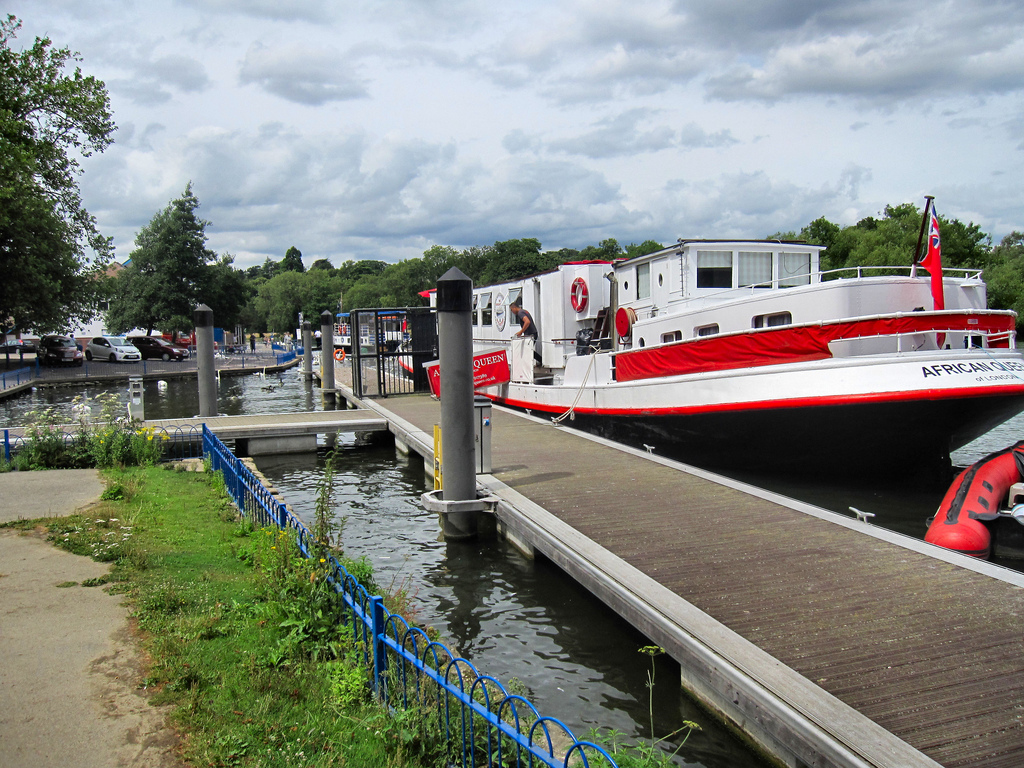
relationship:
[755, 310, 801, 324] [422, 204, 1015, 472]
window on ship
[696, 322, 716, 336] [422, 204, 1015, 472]
window on ship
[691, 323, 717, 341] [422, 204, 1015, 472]
window on ship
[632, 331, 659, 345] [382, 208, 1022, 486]
glass window on boat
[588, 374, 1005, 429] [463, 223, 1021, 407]
red trim on boat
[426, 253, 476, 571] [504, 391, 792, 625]
post on walkway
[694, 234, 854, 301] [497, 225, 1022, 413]
window on boat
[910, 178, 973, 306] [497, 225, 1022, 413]
flag on boat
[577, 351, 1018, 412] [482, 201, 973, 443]
white trim on a boat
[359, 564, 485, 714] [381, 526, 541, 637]
blue wire fence along river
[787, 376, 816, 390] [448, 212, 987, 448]
white red and black river boat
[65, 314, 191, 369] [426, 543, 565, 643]
cars parked at edge of river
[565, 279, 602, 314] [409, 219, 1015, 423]
round life ring hanging on boat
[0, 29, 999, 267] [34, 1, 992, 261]
clouds in sky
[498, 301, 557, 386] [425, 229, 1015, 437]
man standing on boat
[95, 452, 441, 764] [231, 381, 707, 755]
grass near water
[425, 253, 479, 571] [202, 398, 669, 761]
post in water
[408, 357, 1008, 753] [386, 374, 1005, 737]
board on dock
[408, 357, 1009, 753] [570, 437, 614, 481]
board on dock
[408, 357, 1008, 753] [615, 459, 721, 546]
board on dock